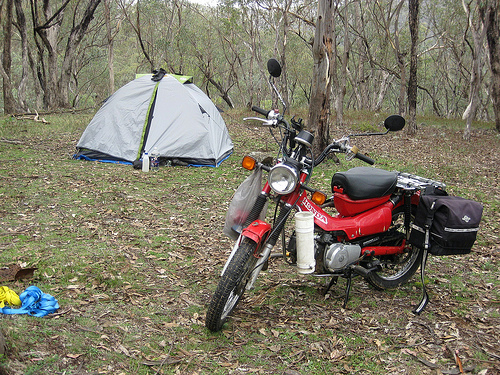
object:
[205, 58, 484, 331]
motorcycle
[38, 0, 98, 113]
tree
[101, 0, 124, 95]
tree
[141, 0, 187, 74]
tree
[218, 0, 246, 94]
tree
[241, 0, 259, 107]
tree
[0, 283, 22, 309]
item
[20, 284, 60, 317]
item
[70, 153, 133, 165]
blue tarp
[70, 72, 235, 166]
gray tent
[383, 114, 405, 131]
mirror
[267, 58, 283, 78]
mirror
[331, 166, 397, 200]
seat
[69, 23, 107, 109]
trees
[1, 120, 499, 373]
grass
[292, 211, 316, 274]
bottles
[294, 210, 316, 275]
tube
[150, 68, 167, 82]
glove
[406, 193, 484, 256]
bag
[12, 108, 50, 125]
branches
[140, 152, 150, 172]
bottle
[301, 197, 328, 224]
honda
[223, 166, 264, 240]
bag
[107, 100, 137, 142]
cloth